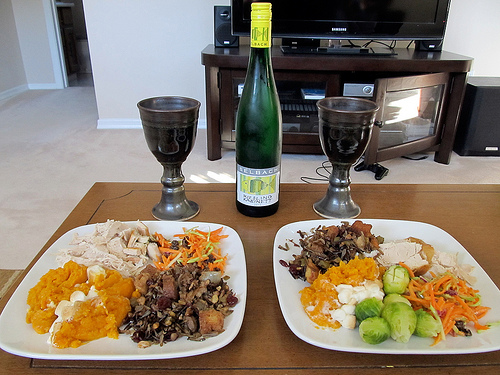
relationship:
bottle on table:
[235, 3, 281, 217] [0, 183, 499, 374]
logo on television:
[331, 26, 349, 33] [231, 3, 454, 53]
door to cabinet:
[364, 73, 450, 165] [203, 40, 473, 166]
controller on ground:
[355, 159, 390, 181] [0, 90, 499, 271]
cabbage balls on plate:
[358, 267, 438, 344] [272, 218, 499, 354]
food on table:
[26, 220, 488, 350] [0, 183, 499, 374]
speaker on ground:
[456, 75, 500, 155] [0, 90, 499, 271]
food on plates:
[26, 220, 488, 350] [0, 220, 499, 361]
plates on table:
[0, 220, 499, 361] [0, 183, 499, 374]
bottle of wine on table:
[235, 3, 281, 217] [0, 183, 499, 374]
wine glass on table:
[137, 97, 201, 222] [0, 183, 499, 374]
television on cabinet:
[231, 3, 454, 53] [203, 40, 473, 166]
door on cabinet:
[364, 73, 450, 165] [203, 40, 473, 166]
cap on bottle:
[249, 3, 273, 50] [235, 3, 281, 217]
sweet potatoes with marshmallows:
[303, 256, 378, 325] [335, 282, 381, 325]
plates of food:
[0, 220, 499, 361] [26, 220, 488, 350]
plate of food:
[272, 218, 499, 354] [291, 222, 487, 335]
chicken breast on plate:
[380, 240, 458, 275] [272, 218, 499, 354]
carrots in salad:
[435, 302, 477, 324] [409, 277, 487, 333]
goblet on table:
[314, 99, 377, 219] [0, 183, 499, 374]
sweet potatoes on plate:
[303, 256, 378, 325] [272, 218, 499, 354]